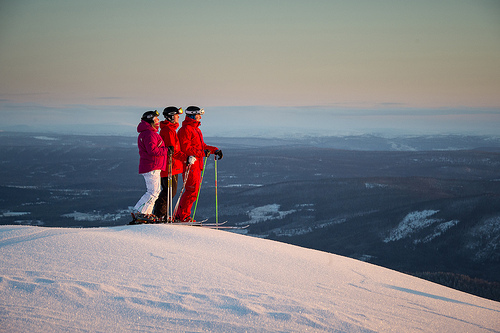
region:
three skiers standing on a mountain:
[130, 89, 225, 229]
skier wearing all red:
[183, 100, 223, 223]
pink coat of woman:
[133, 123, 170, 168]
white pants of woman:
[129, 173, 164, 213]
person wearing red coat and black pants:
[159, 104, 186, 226]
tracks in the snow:
[10, 269, 380, 331]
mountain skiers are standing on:
[7, 217, 489, 332]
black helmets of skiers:
[140, 98, 204, 125]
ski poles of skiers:
[164, 145, 229, 225]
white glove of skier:
[185, 154, 197, 169]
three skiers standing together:
[120, 98, 229, 229]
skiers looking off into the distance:
[133, 94, 222, 217]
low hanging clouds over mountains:
[13, 96, 498, 143]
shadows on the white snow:
[7, 212, 451, 321]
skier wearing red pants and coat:
[175, 119, 215, 221]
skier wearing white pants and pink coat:
[126, 108, 166, 217]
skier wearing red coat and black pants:
[160, 107, 186, 222]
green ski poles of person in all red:
[185, 154, 225, 226]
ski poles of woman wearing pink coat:
[163, 146, 175, 221]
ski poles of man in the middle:
[175, 158, 197, 223]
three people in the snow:
[85, 87, 245, 257]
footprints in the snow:
[82, 257, 227, 322]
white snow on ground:
[160, 231, 248, 271]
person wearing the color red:
[177, 98, 237, 184]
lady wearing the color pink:
[120, 105, 167, 185]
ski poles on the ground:
[185, 167, 241, 207]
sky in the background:
[257, 35, 363, 101]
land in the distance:
[290, 115, 440, 225]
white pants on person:
[121, 165, 168, 225]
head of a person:
[137, 104, 164, 133]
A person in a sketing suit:
[176, 105, 211, 226]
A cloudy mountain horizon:
[318, 126, 419, 146]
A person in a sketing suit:
[135, 105, 160, 220]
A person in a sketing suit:
[162, 100, 184, 217]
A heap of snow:
[78, 222, 293, 328]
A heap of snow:
[1, 225, 52, 325]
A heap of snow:
[336, 245, 426, 328]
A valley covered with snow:
[255, 185, 310, 240]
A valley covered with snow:
[67, 212, 127, 224]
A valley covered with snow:
[375, 203, 480, 248]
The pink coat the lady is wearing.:
[134, 123, 166, 170]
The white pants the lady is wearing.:
[135, 173, 159, 215]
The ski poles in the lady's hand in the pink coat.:
[161, 150, 174, 225]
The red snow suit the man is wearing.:
[179, 116, 201, 219]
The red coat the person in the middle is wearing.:
[160, 118, 184, 176]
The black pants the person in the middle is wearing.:
[160, 165, 175, 213]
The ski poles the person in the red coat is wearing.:
[179, 159, 191, 227]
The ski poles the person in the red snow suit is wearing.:
[191, 152, 218, 229]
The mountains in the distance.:
[15, 107, 499, 183]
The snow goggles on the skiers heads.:
[146, 103, 207, 118]